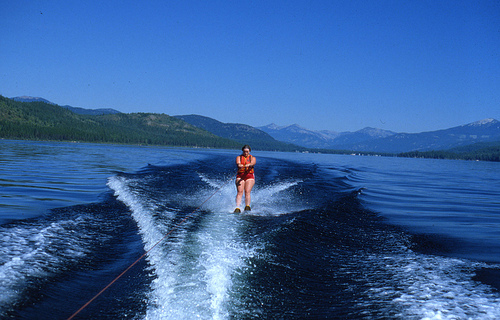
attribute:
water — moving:
[186, 240, 248, 303]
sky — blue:
[231, 21, 322, 90]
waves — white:
[260, 181, 278, 216]